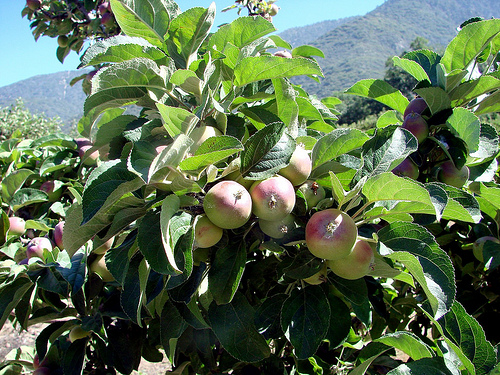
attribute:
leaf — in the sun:
[72, 28, 162, 59]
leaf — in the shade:
[196, 296, 274, 365]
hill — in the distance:
[4, 1, 404, 132]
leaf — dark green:
[80, 156, 138, 216]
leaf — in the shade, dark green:
[276, 282, 333, 363]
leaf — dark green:
[369, 220, 457, 325]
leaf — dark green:
[415, 294, 498, 373]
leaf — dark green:
[324, 288, 356, 351]